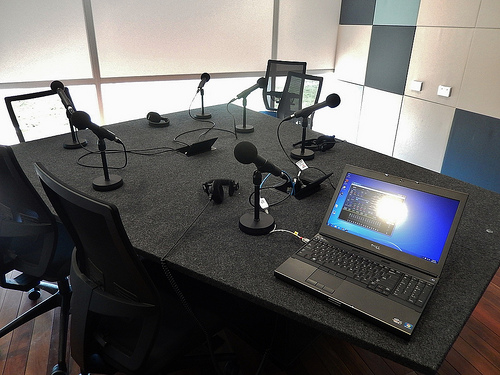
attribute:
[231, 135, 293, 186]
microphone —  black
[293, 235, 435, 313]
keyboard — black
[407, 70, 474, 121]
switch — a light switch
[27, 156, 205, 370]
chair — black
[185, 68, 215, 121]
microphone — black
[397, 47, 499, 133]
wall — in boxes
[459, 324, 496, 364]
floor —  wooden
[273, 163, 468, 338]
laptop —   open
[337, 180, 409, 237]
document —  open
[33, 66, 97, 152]
microphone — black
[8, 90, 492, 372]
table —  dark grey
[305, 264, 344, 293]
pad — black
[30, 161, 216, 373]
chair —  black, black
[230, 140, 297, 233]
microphone — black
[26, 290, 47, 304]
wheel —  chair's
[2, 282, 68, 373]
floor —  wooden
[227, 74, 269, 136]
microphone — black